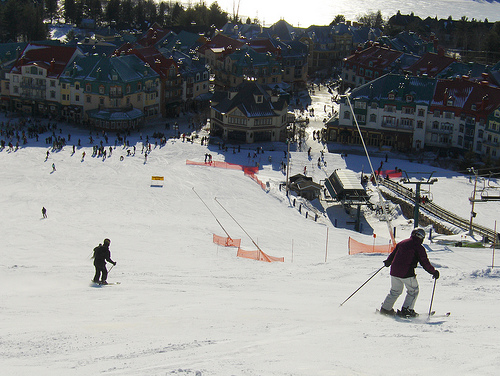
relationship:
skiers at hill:
[50, 162, 57, 169] [6, 145, 210, 189]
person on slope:
[379, 226, 440, 319] [319, 261, 499, 362]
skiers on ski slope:
[6, 124, 177, 167] [1, 247, 500, 373]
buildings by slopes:
[6, 50, 499, 147] [8, 145, 496, 374]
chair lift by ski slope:
[417, 187, 433, 205] [356, 164, 474, 251]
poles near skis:
[334, 261, 440, 327] [367, 309, 455, 329]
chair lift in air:
[467, 173, 498, 203] [431, 146, 499, 254]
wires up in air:
[343, 89, 399, 231] [301, 55, 442, 214]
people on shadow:
[2, 118, 178, 175] [6, 110, 205, 146]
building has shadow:
[6, 27, 169, 120] [6, 110, 205, 146]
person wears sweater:
[379, 226, 440, 319] [381, 236, 438, 278]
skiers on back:
[50, 162, 57, 169] [11, 112, 485, 148]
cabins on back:
[10, 12, 492, 145] [13, 37, 490, 137]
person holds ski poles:
[379, 226, 440, 319] [334, 265, 442, 322]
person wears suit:
[91, 238, 117, 287] [87, 244, 112, 278]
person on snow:
[376, 222, 446, 322] [302, 255, 476, 361]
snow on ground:
[0, 83, 499, 374] [1, 121, 495, 373]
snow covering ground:
[149, 275, 272, 364] [0, 83, 496, 373]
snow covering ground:
[0, 83, 499, 374] [0, 83, 496, 373]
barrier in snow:
[213, 233, 284, 263] [1, 117, 499, 374]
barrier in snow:
[213, 233, 284, 263] [49, 239, 281, 353]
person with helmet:
[379, 226, 440, 319] [408, 226, 428, 239]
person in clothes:
[91, 238, 117, 287] [94, 243, 112, 279]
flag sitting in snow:
[149, 174, 163, 182] [138, 283, 286, 351]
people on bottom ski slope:
[1, 112, 276, 169] [1, 83, 496, 373]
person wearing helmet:
[379, 226, 440, 319] [409, 228, 427, 241]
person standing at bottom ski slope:
[40, 205, 50, 220] [1, 83, 496, 373]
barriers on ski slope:
[210, 230, 286, 262] [1, 83, 496, 373]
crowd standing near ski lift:
[1, 102, 405, 175] [286, 117, 309, 144]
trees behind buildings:
[3, 2, 225, 43] [324, 72, 499, 161]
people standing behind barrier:
[199, 153, 217, 164] [187, 158, 264, 173]